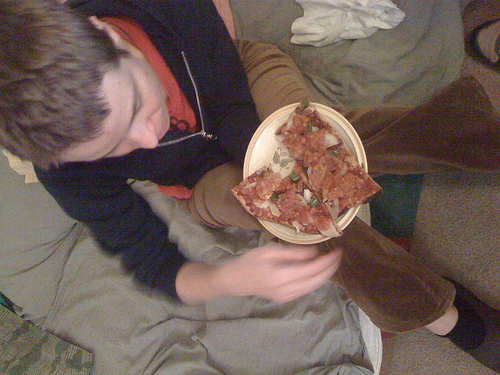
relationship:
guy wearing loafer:
[0, 0, 500, 370] [440, 277, 499, 373]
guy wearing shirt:
[0, 0, 500, 370] [91, 14, 199, 152]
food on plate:
[226, 103, 383, 236] [238, 100, 371, 245]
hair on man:
[2, 2, 122, 162] [3, 3, 476, 336]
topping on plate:
[288, 173, 300, 178] [223, 105, 375, 247]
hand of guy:
[233, 241, 342, 305] [0, 0, 500, 370]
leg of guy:
[341, 232, 460, 337] [0, 0, 500, 370]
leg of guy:
[361, 105, 498, 178] [0, 0, 500, 370]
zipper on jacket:
[158, 52, 215, 148] [32, 0, 261, 303]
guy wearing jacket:
[0, 0, 500, 370] [1, 13, 348, 310]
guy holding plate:
[0, 0, 500, 370] [238, 100, 371, 245]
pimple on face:
[141, 70, 151, 76] [64, 48, 169, 168]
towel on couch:
[289, 0, 407, 47] [2, 0, 467, 374]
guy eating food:
[11, 6, 492, 361] [235, 99, 375, 242]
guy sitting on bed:
[0, 0, 500, 370] [0, 0, 483, 372]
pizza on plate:
[230, 155, 341, 241] [238, 100, 371, 245]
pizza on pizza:
[230, 99, 382, 240] [230, 155, 341, 241]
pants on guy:
[179, 39, 499, 333] [0, 0, 500, 370]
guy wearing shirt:
[0, 0, 500, 370] [91, 14, 198, 200]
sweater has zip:
[34, 29, 267, 313] [160, 53, 221, 153]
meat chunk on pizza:
[276, 192, 306, 218] [230, 147, 342, 238]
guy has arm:
[0, 0, 500, 370] [43, 187, 221, 300]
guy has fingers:
[0, 0, 500, 370] [264, 238, 341, 298]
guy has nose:
[0, 0, 500, 370] [130, 116, 165, 156]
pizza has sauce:
[230, 99, 382, 240] [337, 177, 372, 197]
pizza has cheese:
[230, 99, 382, 240] [325, 132, 337, 146]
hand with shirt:
[233, 241, 342, 305] [44, 3, 244, 305]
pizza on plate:
[230, 99, 382, 240] [238, 100, 371, 245]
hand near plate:
[225, 238, 342, 305] [238, 100, 371, 245]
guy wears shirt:
[0, 0, 500, 370] [177, 101, 192, 130]